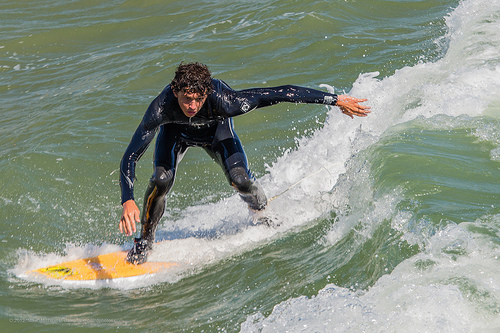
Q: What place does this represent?
A: It represents the ocean.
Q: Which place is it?
A: It is an ocean.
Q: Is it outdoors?
A: Yes, it is outdoors.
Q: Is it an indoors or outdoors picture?
A: It is outdoors.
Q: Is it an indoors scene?
A: No, it is outdoors.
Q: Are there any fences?
A: No, there are no fences.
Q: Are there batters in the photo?
A: No, there are no batters.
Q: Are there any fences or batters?
A: No, there are no batters or fences.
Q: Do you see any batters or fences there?
A: No, there are no batters or fences.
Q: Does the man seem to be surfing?
A: Yes, the man is surfing.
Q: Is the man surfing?
A: Yes, the man is surfing.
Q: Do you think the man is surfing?
A: Yes, the man is surfing.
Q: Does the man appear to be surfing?
A: Yes, the man is surfing.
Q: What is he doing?
A: The man is surfing.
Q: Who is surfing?
A: The man is surfing.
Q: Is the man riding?
A: No, the man is surfing.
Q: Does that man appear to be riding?
A: No, the man is surfing.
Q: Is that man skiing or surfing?
A: The man is surfing.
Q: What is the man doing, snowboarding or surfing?
A: The man is surfing.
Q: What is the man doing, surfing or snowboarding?
A: The man is surfing.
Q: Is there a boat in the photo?
A: No, there are no boats.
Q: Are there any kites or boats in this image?
A: No, there are no boats or kites.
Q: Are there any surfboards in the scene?
A: Yes, there is a surfboard.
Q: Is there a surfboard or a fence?
A: Yes, there is a surfboard.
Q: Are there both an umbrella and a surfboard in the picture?
A: No, there is a surfboard but no umbrellas.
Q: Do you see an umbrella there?
A: No, there are no umbrellas.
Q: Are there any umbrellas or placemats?
A: No, there are no umbrellas or placemats.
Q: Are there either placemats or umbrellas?
A: No, there are no umbrellas or placemats.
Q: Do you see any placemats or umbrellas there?
A: No, there are no umbrellas or placemats.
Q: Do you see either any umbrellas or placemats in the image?
A: No, there are no umbrellas or placemats.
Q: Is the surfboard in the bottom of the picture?
A: Yes, the surfboard is in the bottom of the image.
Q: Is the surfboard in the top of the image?
A: No, the surfboard is in the bottom of the image.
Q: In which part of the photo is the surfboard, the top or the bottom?
A: The surfboard is in the bottom of the image.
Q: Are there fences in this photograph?
A: No, there are no fences.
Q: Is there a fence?
A: No, there are no fences.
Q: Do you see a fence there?
A: No, there are no fences.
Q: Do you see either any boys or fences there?
A: No, there are no fences or boys.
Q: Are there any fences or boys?
A: No, there are no fences or boys.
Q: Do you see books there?
A: No, there are no books.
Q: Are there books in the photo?
A: No, there are no books.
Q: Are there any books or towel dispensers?
A: No, there are no books or towel dispensers.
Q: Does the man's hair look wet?
A: Yes, the hair is wet.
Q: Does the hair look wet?
A: Yes, the hair is wet.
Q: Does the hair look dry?
A: No, the hair is wet.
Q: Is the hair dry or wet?
A: The hair is wet.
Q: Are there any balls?
A: No, there are no balls.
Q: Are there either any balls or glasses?
A: No, there are no balls or glasses.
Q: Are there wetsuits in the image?
A: Yes, there is a wetsuit.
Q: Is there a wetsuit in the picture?
A: Yes, there is a wetsuit.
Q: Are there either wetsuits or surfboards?
A: Yes, there is a wetsuit.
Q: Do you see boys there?
A: No, there are no boys.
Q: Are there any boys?
A: No, there are no boys.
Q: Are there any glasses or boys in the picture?
A: No, there are no boys or glasses.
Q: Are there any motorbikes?
A: No, there are no motorbikes.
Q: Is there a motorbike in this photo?
A: No, there are no motorcycles.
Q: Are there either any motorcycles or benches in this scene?
A: No, there are no motorcycles or benches.